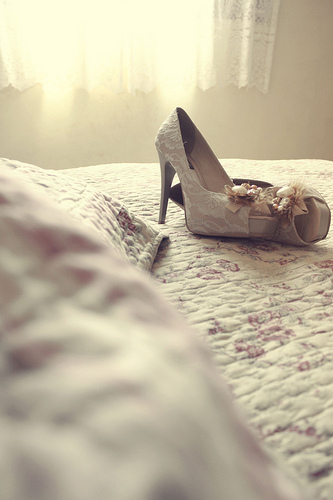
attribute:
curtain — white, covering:
[17, 6, 278, 100]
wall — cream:
[12, 2, 331, 166]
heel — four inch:
[155, 163, 177, 218]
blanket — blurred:
[9, 161, 332, 498]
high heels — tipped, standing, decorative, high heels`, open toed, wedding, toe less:
[157, 106, 332, 247]